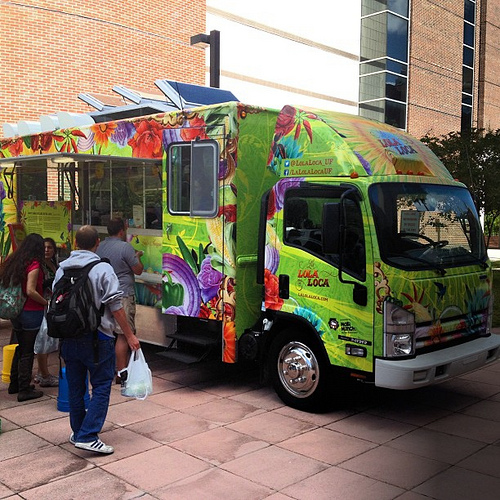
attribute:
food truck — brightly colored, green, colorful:
[1, 77, 499, 414]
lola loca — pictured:
[297, 268, 333, 291]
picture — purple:
[161, 253, 228, 322]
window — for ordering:
[83, 158, 163, 239]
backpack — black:
[44, 256, 116, 365]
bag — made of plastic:
[123, 349, 157, 403]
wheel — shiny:
[267, 322, 336, 416]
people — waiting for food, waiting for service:
[2, 214, 145, 461]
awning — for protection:
[2, 153, 166, 176]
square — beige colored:
[1, 422, 53, 465]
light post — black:
[186, 24, 225, 91]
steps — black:
[156, 328, 219, 369]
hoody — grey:
[50, 250, 126, 341]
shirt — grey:
[96, 235, 146, 295]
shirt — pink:
[15, 263, 46, 311]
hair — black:
[46, 237, 60, 270]